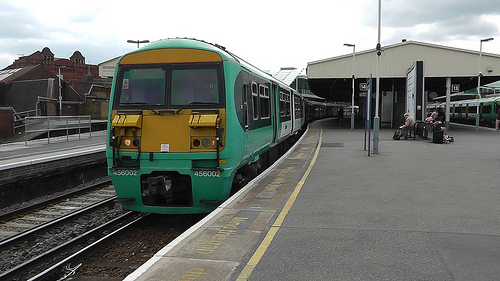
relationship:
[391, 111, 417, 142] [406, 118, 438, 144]
person sitting on bench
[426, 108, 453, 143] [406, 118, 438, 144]
person sitting on bench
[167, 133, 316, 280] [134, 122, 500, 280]
letters on cement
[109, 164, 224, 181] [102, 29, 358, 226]
letters on train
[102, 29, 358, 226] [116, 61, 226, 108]
train has windows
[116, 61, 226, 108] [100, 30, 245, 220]
windows are on front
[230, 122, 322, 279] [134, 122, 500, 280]
line on cement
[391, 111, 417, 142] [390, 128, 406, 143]
person has belongings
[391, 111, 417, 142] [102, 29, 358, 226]
person waiting for train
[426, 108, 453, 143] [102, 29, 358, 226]
person waiting for train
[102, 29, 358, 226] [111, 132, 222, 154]
train has head lights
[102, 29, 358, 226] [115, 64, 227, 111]
train has windshield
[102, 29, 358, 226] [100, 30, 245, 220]
train has front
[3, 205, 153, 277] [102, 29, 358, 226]
train tracks under train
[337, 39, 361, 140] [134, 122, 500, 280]
street light on cement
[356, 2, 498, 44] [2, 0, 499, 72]
cloud in sky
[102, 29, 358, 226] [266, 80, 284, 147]
train has door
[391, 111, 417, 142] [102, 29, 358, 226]
person waiting on train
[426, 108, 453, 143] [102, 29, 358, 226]
person waiting on train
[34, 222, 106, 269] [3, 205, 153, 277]
part of train tracks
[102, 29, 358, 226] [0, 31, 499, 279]
train at train station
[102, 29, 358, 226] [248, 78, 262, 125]
train has window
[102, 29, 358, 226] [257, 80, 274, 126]
train has window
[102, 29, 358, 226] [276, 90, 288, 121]
train has window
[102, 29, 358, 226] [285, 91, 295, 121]
train has window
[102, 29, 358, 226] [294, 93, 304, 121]
train has window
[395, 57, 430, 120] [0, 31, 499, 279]
post at train station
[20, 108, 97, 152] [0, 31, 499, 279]
safety rail at train station